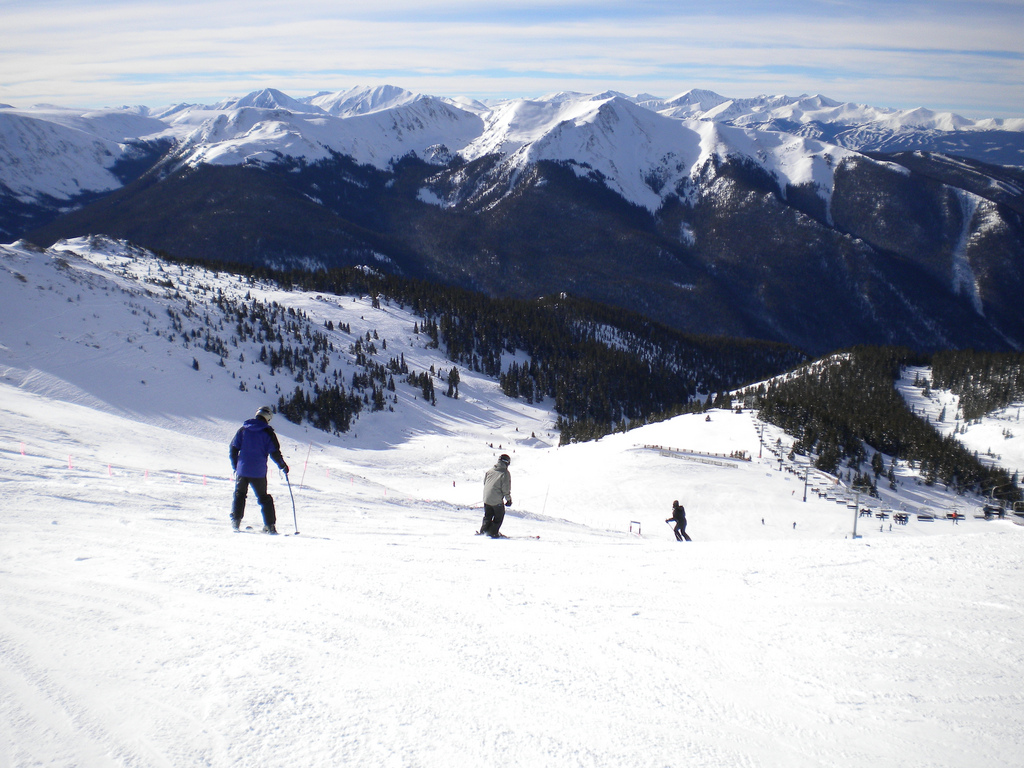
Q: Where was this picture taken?
A: On snow.